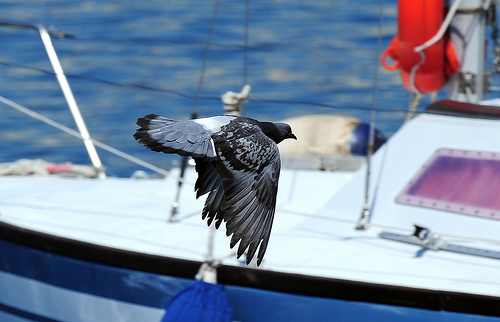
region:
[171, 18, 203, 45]
part of a water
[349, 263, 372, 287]
edge of a boat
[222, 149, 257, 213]
part of a birrd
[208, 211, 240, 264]
edge of a winmg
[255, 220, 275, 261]
edge of a wing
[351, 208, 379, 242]
part of a ,etal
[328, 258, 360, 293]
edge of a boat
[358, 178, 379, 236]
part of a metal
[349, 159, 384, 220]
part of a metal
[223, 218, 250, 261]
edge of a wing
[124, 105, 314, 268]
A bird in mid flight.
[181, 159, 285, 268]
A bird's wings.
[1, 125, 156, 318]
The deck of a boat in the back ground.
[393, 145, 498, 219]
A window of a boat.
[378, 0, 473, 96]
An orange float for a person.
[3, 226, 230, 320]
The side of the boat with multi colored stripes.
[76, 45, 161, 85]
The ocean in the back ground.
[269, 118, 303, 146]
The head of the bird in mid flight.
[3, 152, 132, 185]
A thing of ropes in the deck of the boat.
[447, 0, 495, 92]
The pole the sale goes on.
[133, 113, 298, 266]
Bird flying over the water near a boat.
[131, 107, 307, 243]
bird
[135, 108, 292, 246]
bird flying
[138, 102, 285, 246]
black bird blying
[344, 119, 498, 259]
white window of boat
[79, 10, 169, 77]
white clouds in light blue sky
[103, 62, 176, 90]
white clouds in light blue sky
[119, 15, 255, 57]
white clouds in light blue sky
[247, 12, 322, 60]
white clouds in light blue sky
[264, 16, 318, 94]
white clouds in light blue sky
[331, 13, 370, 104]
white clouds in light blue sky